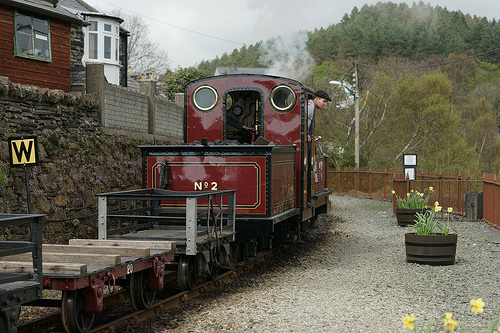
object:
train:
[132, 68, 335, 241]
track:
[1, 209, 320, 332]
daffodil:
[407, 200, 456, 237]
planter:
[402, 231, 461, 268]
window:
[191, 84, 220, 113]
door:
[302, 94, 314, 208]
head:
[313, 90, 332, 110]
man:
[307, 86, 334, 142]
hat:
[314, 89, 334, 102]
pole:
[354, 61, 360, 171]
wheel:
[55, 283, 102, 333]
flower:
[464, 296, 489, 317]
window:
[11, 11, 55, 63]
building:
[0, 0, 133, 93]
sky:
[83, 0, 499, 73]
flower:
[390, 189, 397, 195]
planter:
[394, 207, 432, 227]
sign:
[403, 153, 417, 166]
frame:
[402, 152, 419, 167]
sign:
[4, 134, 42, 167]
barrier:
[85, 62, 187, 141]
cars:
[0, 180, 244, 333]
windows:
[83, 30, 101, 61]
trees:
[481, 18, 499, 67]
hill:
[145, 0, 500, 181]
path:
[153, 194, 499, 332]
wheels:
[123, 256, 162, 313]